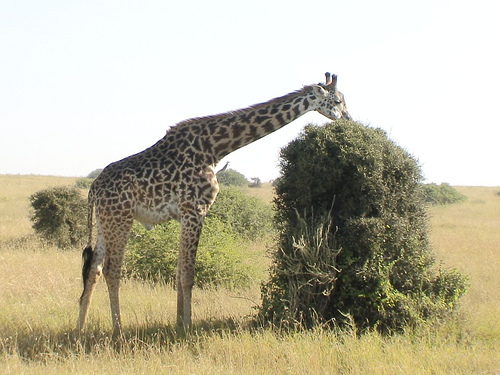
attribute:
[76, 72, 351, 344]
giraffe — standing, walking, in the daytime, eating, in the open, watching for danger, tall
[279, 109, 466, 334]
tree — green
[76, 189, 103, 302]
tail — black, brown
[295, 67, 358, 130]
head — black, brown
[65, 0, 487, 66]
sky — hazy